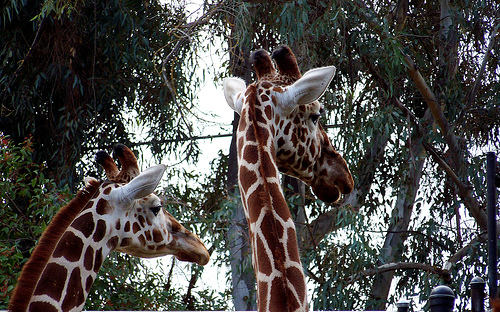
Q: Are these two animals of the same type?
A: Yes, all the animals are giraffes.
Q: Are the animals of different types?
A: No, all the animals are giraffes.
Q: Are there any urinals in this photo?
A: No, there are no urinals.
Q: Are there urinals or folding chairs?
A: No, there are no urinals or folding chairs.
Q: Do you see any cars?
A: No, there are no cars.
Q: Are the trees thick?
A: Yes, the trees are thick.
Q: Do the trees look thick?
A: Yes, the trees are thick.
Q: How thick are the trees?
A: The trees are thick.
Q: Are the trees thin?
A: No, the trees are thick.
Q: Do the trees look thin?
A: No, the trees are thick.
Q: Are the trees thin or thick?
A: The trees are thick.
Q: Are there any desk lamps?
A: No, there are no desk lamps.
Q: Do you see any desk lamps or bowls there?
A: No, there are no desk lamps or bowls.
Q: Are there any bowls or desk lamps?
A: No, there are no desk lamps or bowls.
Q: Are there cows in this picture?
A: No, there are no cows.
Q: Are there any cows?
A: No, there are no cows.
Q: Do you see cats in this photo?
A: No, there are no cats.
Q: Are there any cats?
A: No, there are no cats.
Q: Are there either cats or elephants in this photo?
A: No, there are no cats or elephants.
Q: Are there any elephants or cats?
A: No, there are no cats or elephants.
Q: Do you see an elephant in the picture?
A: No, there are no elephants.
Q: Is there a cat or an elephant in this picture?
A: No, there are no elephants or cats.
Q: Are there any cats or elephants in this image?
A: No, there are no elephants or cats.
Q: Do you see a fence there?
A: Yes, there is a fence.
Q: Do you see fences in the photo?
A: Yes, there is a fence.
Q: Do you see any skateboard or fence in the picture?
A: Yes, there is a fence.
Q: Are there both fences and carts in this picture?
A: No, there is a fence but no carts.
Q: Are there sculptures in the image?
A: No, there are no sculptures.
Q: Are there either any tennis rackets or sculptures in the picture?
A: No, there are no sculptures or tennis rackets.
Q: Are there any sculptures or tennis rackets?
A: No, there are no sculptures or tennis rackets.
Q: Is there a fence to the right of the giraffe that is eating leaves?
A: Yes, there is a fence to the right of the giraffe.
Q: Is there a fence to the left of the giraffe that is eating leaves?
A: No, the fence is to the right of the giraffe.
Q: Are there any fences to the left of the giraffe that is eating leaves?
A: No, the fence is to the right of the giraffe.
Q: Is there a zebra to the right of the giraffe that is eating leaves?
A: No, there is a fence to the right of the giraffe.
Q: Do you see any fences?
A: Yes, there is a fence.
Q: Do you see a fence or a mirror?
A: Yes, there is a fence.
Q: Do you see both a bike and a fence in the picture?
A: No, there is a fence but no bikes.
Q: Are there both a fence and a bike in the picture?
A: No, there is a fence but no bikes.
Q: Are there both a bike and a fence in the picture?
A: No, there is a fence but no bikes.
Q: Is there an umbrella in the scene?
A: No, there are no umbrellas.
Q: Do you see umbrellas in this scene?
A: No, there are no umbrellas.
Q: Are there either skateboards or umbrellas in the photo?
A: No, there are no umbrellas or skateboards.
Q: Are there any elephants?
A: No, there are no elephants.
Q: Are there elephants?
A: No, there are no elephants.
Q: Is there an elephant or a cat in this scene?
A: No, there are no elephants or cats.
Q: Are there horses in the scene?
A: No, there are no horses.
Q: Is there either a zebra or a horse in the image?
A: No, there are no horses or zebras.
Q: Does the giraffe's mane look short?
A: Yes, the mane is short.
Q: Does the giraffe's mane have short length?
A: Yes, the mane is short.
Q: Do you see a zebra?
A: No, there are no zebras.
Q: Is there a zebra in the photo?
A: No, there are no zebras.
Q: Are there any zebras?
A: No, there are no zebras.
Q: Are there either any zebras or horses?
A: No, there are no zebras or horses.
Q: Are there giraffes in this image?
A: Yes, there is a giraffe.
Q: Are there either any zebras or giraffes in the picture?
A: Yes, there is a giraffe.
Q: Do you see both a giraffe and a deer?
A: No, there is a giraffe but no deer.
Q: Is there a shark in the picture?
A: No, there are no sharks.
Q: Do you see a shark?
A: No, there are no sharks.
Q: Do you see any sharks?
A: No, there are no sharks.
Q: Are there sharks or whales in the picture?
A: No, there are no sharks or whales.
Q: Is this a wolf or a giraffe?
A: This is a giraffe.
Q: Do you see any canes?
A: No, there are no canes.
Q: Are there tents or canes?
A: No, there are no canes or tents.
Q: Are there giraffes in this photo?
A: Yes, there is a giraffe.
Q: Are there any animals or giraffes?
A: Yes, there is a giraffe.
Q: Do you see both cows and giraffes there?
A: No, there is a giraffe but no cows.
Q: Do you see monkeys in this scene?
A: No, there are no monkeys.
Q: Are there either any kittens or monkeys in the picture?
A: No, there are no monkeys or kittens.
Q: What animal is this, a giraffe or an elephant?
A: This is a giraffe.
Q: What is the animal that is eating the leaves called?
A: The animal is a giraffe.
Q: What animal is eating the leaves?
A: The animal is a giraffe.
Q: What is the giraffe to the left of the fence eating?
A: The giraffe is eating leaves.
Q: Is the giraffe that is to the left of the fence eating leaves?
A: Yes, the giraffe is eating leaves.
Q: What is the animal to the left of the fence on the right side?
A: The animal is a giraffe.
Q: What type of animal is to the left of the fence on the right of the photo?
A: The animal is a giraffe.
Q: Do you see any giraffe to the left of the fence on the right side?
A: Yes, there is a giraffe to the left of the fence.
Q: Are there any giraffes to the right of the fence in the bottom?
A: No, the giraffe is to the left of the fence.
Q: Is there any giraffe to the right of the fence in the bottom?
A: No, the giraffe is to the left of the fence.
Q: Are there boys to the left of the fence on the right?
A: No, there is a giraffe to the left of the fence.